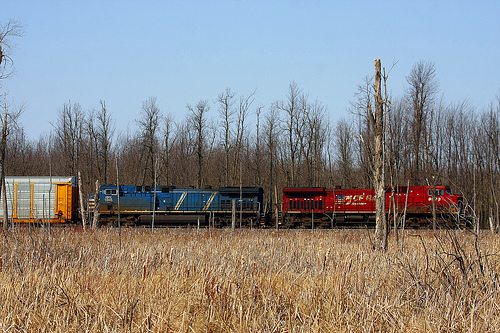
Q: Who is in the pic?
A: No one.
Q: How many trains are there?
A: 1.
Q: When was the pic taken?
A: During the day.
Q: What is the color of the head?
A: Red.